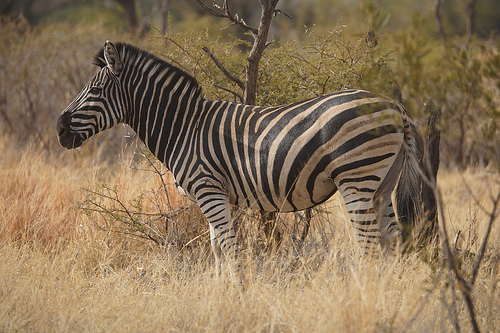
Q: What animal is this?
A: Zebra.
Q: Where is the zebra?
A: Weedy field.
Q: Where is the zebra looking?
A: Left.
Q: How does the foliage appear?
A: Dry.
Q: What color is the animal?
A: Black and white.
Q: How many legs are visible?
A: 3.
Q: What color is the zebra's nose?
A: Black.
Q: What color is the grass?
A: Brown.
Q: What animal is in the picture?
A: Zebra.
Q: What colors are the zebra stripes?
A: Black and white.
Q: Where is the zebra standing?
A: In a field.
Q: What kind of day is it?
A: Sunny.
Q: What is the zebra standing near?
A: Tree branches.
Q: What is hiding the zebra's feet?
A: Grass.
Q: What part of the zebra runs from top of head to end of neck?
A: Mane.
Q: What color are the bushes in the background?
A: Green.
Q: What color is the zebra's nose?
A: Black.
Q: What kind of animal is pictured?
A: Zebra.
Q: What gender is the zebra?
A: Female.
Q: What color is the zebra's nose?
A: Black.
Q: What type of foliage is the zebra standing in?
A: Brush.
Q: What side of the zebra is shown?
A: The left.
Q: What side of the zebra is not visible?
A: Right.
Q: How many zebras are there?
A: 1.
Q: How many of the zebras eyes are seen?
A: 1.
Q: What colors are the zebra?
A: Black and white.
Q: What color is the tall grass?
A: Brown.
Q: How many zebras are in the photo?
A: One.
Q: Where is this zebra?
A: Savannah.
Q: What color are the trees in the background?
A: Green.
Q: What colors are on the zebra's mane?
A: Black and white.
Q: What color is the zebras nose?
A: Black.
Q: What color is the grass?
A: Tall and brown.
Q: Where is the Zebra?
A: In a field.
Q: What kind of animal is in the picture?
A: A zebra.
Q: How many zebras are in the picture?
A: 1.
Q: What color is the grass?
A: Brown.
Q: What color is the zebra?
A: Black and white.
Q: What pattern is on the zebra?
A: Stripes.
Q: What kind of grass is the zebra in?
A: Tall grass.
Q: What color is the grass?
A: Brown.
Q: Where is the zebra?
A: In the wild.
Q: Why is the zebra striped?
A: For camoflauge.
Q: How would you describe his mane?
A: Short and stiff.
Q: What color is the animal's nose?
A: Black.